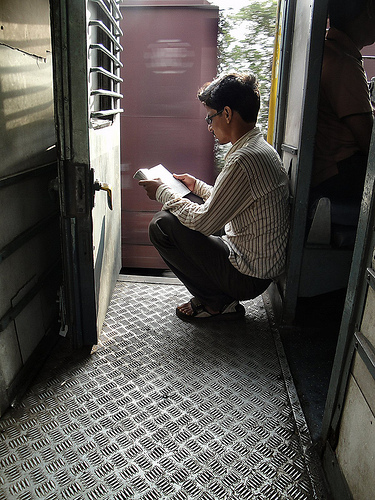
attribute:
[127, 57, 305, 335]
man — crouch, crouched, poor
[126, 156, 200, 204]
book — open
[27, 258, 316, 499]
floor — metal, rigid, grey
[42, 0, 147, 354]
door — open, older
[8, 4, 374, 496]
train car — day time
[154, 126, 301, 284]
shirt — striped, long sleeve, brown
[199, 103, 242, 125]
glasses — black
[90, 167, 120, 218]
handle — yellow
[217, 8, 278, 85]
trees — green